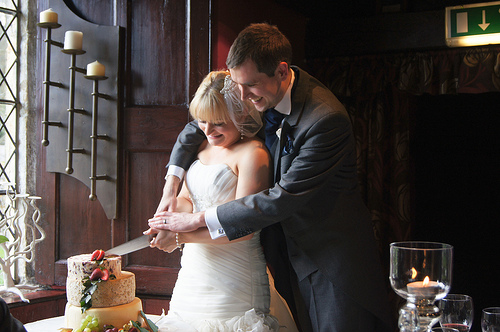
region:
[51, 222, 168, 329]
Knife cutting a cake.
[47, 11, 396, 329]
Couple cutting the wedding cake.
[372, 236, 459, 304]
Candle in the glass.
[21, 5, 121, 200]
Candles hanging on the wall.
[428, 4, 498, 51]
Sign hanging on the wall.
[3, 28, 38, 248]
Window on the left side.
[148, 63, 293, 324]
Woman wearing a wedding dress.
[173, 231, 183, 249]
Pearls on a woman's wrist.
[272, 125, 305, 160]
Flower on a man's suit.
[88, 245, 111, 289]
Fruit on a cake.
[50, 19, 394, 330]
couple cutting a wedding cake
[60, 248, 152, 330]
wedding cake with flowers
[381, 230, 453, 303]
candle in a glass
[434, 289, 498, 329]
top of wineglasses on the table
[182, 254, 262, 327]
bottom of the wedding dress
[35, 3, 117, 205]
three candles on the wall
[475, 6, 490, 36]
arrow facing down on the sign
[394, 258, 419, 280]
glares of the candle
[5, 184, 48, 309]
decorative white tree on the window sill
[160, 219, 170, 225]
wedding ring on a finger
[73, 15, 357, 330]
couple cutting the cake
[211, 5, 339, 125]
the head of a man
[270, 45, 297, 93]
the ear of a man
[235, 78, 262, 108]
the nose of a man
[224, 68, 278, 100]
the eyes of a man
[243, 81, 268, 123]
the mouth of a man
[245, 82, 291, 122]
the lips of a man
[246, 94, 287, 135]
the chin of a man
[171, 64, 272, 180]
the head of a woman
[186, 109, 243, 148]
the nose of a woman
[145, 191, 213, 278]
the hand of a man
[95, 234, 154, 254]
part of a large knife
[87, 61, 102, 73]
a beige candle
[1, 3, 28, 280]
part of a long window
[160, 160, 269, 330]
part of a woman's white dress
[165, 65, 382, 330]
a man's black suit coat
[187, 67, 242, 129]
part of a woman's blonde hair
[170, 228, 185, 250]
a woman's white bracelet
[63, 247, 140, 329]
a small layered cake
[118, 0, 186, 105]
part of a wooden wall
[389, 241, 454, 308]
a large glass candle holder